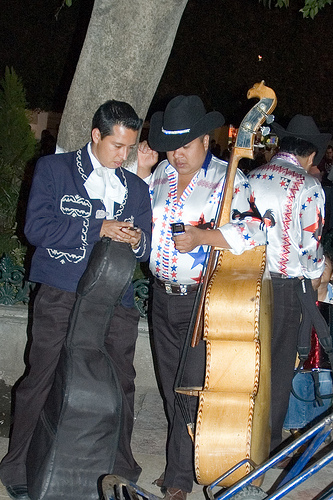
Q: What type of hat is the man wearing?
A: Cowboy.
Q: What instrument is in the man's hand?
A: A cello.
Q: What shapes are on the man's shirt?
A: Stars.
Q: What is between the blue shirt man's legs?
A: A cello case.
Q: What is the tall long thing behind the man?
A: A tree trunk.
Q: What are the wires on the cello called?
A: Strings.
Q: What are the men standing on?
A: Concrete.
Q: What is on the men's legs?
A: Pants.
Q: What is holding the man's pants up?
A: A belt.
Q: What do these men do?
A: Play music.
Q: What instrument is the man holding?
A: Upright bass.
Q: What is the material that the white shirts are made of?
A: Silk.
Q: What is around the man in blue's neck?
A: Scarf.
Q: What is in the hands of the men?
A: Cell phones.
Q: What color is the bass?
A: Brown.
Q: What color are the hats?
A: Black.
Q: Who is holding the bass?
A: The man in the middle.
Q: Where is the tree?
A: Behind the men.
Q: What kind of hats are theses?
A: Cowboy hats.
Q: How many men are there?
A: Three.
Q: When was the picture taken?
A: At night.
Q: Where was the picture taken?
A: Outside at a concert.